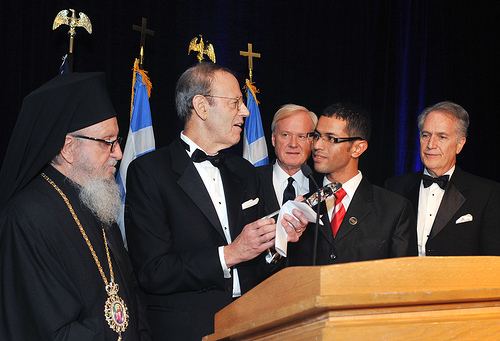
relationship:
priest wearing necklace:
[3, 67, 153, 339] [41, 165, 135, 340]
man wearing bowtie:
[119, 58, 303, 340] [190, 146, 223, 168]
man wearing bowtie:
[361, 96, 499, 257] [190, 146, 223, 168]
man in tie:
[277, 98, 419, 273] [328, 188, 345, 242]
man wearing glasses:
[119, 58, 303, 340] [198, 86, 246, 112]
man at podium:
[119, 58, 303, 340] [195, 249, 498, 339]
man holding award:
[119, 58, 303, 340] [252, 174, 345, 268]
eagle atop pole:
[47, 5, 94, 37] [65, 26, 76, 73]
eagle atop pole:
[182, 29, 217, 63] [195, 53, 204, 67]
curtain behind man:
[3, 1, 499, 204] [119, 58, 303, 340]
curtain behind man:
[3, 1, 499, 204] [361, 96, 499, 257]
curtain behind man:
[3, 1, 499, 204] [277, 98, 419, 273]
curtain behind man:
[3, 1, 499, 204] [253, 98, 323, 286]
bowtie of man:
[419, 171, 452, 196] [361, 96, 499, 257]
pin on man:
[346, 214, 358, 228] [277, 98, 419, 273]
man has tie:
[277, 98, 419, 273] [328, 188, 345, 242]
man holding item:
[119, 58, 303, 340] [266, 193, 328, 261]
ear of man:
[190, 91, 211, 122] [119, 58, 303, 340]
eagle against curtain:
[47, 5, 94, 37] [3, 1, 499, 204]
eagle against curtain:
[182, 29, 217, 63] [3, 1, 499, 204]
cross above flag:
[235, 43, 264, 78] [241, 77, 273, 177]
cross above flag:
[127, 15, 160, 62] [115, 62, 163, 252]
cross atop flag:
[235, 43, 264, 78] [241, 77, 273, 177]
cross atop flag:
[127, 15, 160, 62] [115, 62, 163, 252]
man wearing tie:
[277, 98, 419, 273] [328, 188, 345, 242]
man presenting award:
[119, 58, 303, 340] [252, 174, 345, 268]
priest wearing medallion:
[3, 67, 153, 339] [101, 284, 133, 335]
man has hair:
[253, 98, 323, 286] [268, 99, 320, 136]